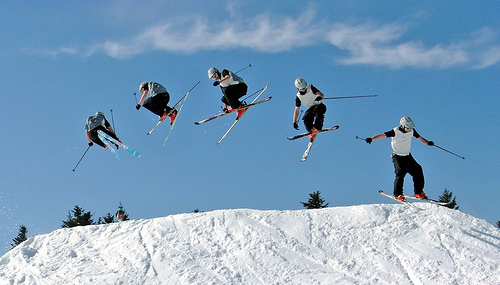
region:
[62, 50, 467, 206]
five images of person during and after an aerial trick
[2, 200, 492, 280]
large snowy mound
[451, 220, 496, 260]
shadow on snow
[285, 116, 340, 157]
skates crossed one over the other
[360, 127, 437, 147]
person's arms extended outwards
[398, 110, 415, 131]
person wearing white helmet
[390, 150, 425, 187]
person wearing dark pants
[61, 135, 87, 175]
ski pole extending to person's left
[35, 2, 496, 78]
wispy cloud in blue sky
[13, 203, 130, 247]
tips of trees visible over snow mound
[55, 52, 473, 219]
There are five skiers.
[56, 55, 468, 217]
The skiers perform acrobatic jumps.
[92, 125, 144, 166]
The skier's skies are blue.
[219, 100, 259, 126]
The skier's boots are red.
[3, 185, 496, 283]
The skiers are on a mountaintop.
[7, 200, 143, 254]
There are trees in the background.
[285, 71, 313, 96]
The skier wears a white helmet.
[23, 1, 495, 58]
There is a cloud in the sky.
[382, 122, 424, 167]
The skier wears a white vest.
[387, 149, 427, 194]
The skier wears black pants.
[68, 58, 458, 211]
multiple views of a man jumping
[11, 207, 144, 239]
trees peeking over the hill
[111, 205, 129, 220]
a dog on the hill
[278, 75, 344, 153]
a man with skis crossed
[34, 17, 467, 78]
light soft clouds in the sky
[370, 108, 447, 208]
a man wearing a white shirt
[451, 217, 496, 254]
shadow of ski's on the snow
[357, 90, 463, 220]
a skier with his arms out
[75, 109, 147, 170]
the backside of a man in the air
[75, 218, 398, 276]
lots of ski tracks in the snow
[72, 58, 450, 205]
Time lapse ski jumping man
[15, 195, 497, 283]
Frequently skied and jumped snowy hill.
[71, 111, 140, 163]
Ski jumping man spinning around.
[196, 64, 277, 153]
Ski jumping man in middle of maneuver.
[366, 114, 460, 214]
Ski jumping man sticks his landing.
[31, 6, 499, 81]
The cloud in the sky is also time lapsed.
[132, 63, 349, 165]
If he crosses his skis there will be pain.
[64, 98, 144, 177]
The bottom of the jumper's skis is blue.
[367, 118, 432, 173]
He has on short sleeves despite the snow.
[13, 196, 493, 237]
He jumped higher than the tree line.